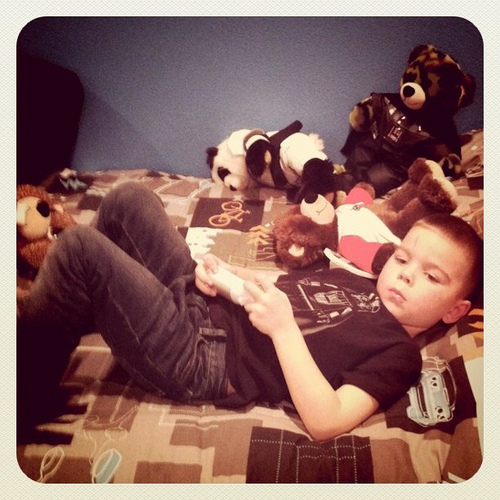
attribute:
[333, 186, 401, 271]
shirt — pink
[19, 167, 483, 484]
sheet — brown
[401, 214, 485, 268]
hair — short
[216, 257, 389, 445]
tshirt — Darth Vader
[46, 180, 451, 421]
boy — holding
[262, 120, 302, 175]
teddybear — wearing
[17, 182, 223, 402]
pant — black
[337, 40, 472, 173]
bear — teddy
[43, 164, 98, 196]
football — drawing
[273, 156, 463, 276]
teddy bear — wearing, white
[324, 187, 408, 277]
shirt — red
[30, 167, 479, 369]
sheet — brown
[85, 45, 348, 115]
wall — blue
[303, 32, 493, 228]
bear. — black, white, teddy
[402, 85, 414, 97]
nose — black